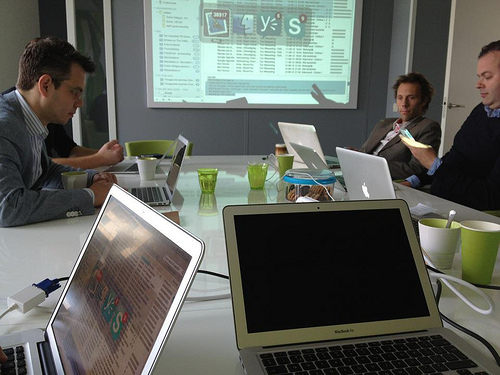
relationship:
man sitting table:
[355, 68, 443, 181] [3, 143, 498, 374]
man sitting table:
[399, 32, 499, 215] [3, 143, 498, 374]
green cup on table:
[459, 210, 498, 287] [183, 140, 493, 287]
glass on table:
[194, 167, 217, 193] [3, 143, 498, 374]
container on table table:
[276, 160, 347, 206] [18, 147, 483, 357]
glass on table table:
[191, 160, 228, 205] [3, 143, 498, 374]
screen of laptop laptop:
[246, 227, 418, 310] [217, 197, 439, 339]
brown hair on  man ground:
[14, 36, 97, 92] [448, 132, 476, 161]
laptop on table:
[103, 120, 206, 220] [3, 143, 498, 374]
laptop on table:
[82, 190, 196, 322] [143, 137, 425, 232]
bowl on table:
[286, 164, 335, 199] [3, 143, 498, 374]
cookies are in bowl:
[287, 181, 332, 198] [286, 164, 335, 199]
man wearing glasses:
[0, 34, 117, 227] [57, 78, 82, 97]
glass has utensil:
[245, 160, 268, 191] [443, 208, 456, 228]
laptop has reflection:
[220, 198, 500, 374] [98, 207, 160, 259]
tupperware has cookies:
[279, 161, 343, 212] [282, 182, 334, 202]